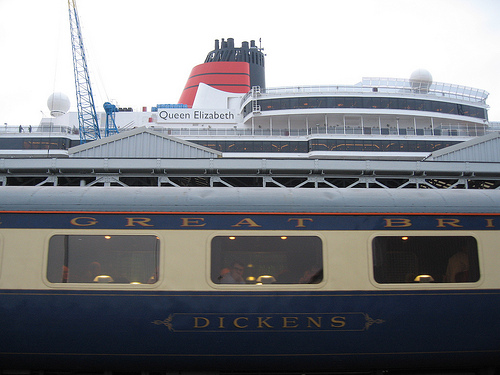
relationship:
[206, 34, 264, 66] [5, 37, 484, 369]
stacks on ship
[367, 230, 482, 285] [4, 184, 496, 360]
windows in train car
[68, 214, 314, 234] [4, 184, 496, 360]
word painted train car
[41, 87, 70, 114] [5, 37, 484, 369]
dome on ship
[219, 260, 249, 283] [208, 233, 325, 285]
passenger looking out window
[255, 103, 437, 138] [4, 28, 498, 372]
windows on boat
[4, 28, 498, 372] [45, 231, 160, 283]
boat has window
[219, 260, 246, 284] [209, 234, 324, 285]
passenger in window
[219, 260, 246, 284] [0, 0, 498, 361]
passenger in boat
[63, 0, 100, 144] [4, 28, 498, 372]
crane above boat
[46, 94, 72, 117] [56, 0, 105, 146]
white circle by crane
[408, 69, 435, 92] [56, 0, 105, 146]
white circle by crane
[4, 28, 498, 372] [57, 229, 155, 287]
boat has 3 windoes